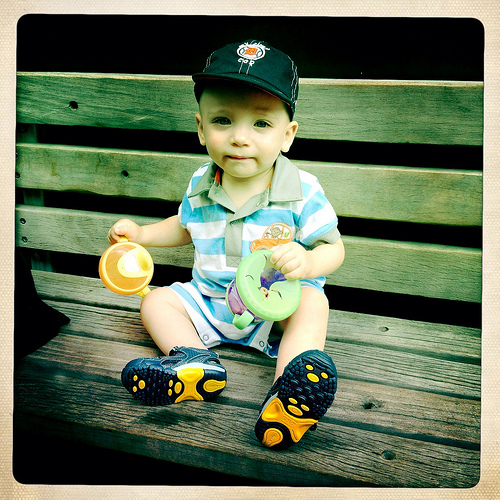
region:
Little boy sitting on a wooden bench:
[35, 20, 473, 483]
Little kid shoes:
[116, 335, 347, 453]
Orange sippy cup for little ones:
[87, 224, 177, 311]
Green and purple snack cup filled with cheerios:
[212, 237, 312, 342]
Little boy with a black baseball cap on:
[170, 30, 310, 172]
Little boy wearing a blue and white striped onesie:
[90, 26, 391, 462]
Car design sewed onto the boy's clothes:
[242, 214, 302, 258]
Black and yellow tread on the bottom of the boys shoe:
[251, 347, 343, 457]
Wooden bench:
[342, 75, 482, 483]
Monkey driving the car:
[257, 219, 290, 244]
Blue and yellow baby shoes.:
[86, 333, 383, 451]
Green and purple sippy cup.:
[191, 223, 316, 338]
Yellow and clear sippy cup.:
[69, 236, 158, 313]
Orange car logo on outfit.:
[223, 221, 321, 263]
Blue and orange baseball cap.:
[124, 32, 342, 117]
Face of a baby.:
[150, 91, 330, 171]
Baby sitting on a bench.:
[38, 79, 399, 450]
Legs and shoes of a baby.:
[73, 287, 378, 457]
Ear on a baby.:
[270, 107, 327, 179]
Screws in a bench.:
[8, 150, 55, 270]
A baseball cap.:
[191, 39, 306, 108]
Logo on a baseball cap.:
[223, 37, 278, 69]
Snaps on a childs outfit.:
[193, 326, 276, 354]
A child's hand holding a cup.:
[214, 251, 310, 332]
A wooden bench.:
[30, 156, 454, 478]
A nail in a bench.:
[360, 393, 385, 418]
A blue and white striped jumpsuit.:
[165, 156, 329, 343]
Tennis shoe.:
[114, 343, 238, 406]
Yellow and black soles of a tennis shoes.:
[241, 350, 342, 463]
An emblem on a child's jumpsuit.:
[240, 220, 306, 265]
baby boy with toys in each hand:
[92, 36, 402, 451]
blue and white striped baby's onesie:
[168, 153, 370, 355]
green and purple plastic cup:
[213, 240, 312, 336]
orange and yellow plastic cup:
[88, 212, 165, 307]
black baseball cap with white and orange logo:
[184, 32, 326, 119]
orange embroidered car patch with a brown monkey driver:
[247, 220, 302, 254]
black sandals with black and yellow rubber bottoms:
[121, 343, 357, 455]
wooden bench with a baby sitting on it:
[17, 31, 487, 493]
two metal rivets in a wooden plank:
[15, 207, 42, 252]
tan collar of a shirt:
[178, 157, 315, 217]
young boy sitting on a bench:
[75, 18, 372, 408]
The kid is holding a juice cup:
[86, 206, 170, 317]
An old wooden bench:
[366, 238, 458, 474]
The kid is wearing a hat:
[131, 28, 339, 192]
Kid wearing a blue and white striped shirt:
[156, 200, 356, 335]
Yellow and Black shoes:
[111, 323, 249, 420]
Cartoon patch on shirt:
[234, 205, 313, 282]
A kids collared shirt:
[176, 143, 318, 225]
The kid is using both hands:
[84, 208, 405, 318]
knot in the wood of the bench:
[373, 436, 398, 465]